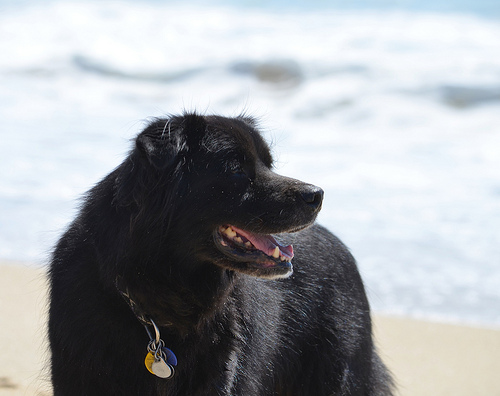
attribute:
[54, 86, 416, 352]
dog' — black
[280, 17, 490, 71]
cloud — white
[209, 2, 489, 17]
sky — blue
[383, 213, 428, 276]
waves — white, green, ocean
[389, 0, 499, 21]
sky — blue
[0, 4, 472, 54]
clouds — white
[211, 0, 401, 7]
sky — blue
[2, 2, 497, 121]
sky — blue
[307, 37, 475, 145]
waves — white, green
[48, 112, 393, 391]
black dog — large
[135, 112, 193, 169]
ear — black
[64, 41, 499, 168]
waves — white, green, ocean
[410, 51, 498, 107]
ocean wave — white, green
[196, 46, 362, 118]
ocean wave — white, green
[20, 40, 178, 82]
ocean wave — white, green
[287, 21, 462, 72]
clouds — white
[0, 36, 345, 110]
ocean waves — white, green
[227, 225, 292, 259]
tongue — pink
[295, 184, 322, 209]
nose — black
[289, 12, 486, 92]
clouds — white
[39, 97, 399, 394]
dog — black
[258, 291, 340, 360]
fur — black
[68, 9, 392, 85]
sky — blue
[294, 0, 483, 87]
clouds — white